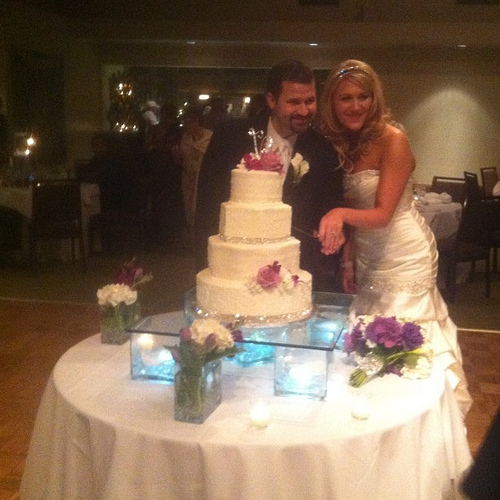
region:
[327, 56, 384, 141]
head of a person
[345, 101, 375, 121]
nose of a person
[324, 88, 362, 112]
eye of a person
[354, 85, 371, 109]
eye of a person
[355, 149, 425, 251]
arm of a person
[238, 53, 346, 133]
head of a person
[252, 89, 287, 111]
ear of a person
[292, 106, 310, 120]
nose of a person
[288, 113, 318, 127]
mouth of a person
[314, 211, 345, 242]
hand of a person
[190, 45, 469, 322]
Bride and groom cutting wedding cake.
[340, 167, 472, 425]
Bride wearing a wedding dress.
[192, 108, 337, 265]
Groom wearing black suit.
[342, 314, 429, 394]
Purple flower bouquet lying on table.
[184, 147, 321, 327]
Four tier wedding cake sitting on table.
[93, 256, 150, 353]
White and purple flowers in vase on table.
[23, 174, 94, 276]
Back of chair pushed up to table.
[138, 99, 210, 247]
Two women standing in background.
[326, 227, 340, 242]
Woman wearing wedding ring on finger.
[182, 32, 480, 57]
Lights mounted in ceiling of room.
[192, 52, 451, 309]
a bride and groom on their wedding day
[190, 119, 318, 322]
a four-tiered wedding cake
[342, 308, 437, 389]
a purple and white floral bouquet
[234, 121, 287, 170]
decorations on top of the wedding cake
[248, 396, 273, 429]
a small candle on the table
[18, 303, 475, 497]
a white tablecloth on the table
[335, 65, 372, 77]
a sparkly headband in the bride's hair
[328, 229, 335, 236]
a ring on the bride's finger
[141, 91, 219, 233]
people coming into the reception hall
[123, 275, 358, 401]
a glass structure with a wedding cake on it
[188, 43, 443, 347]
two people holding a knife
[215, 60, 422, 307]
two married people holding knife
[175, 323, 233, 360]
white flowers in vase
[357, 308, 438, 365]
purple flowers on table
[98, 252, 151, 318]
white and purple flowers in vase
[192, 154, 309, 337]
large white wedding cake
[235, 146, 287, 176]
pink and purple wedding cake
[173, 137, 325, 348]
four tiered wedding cake on stand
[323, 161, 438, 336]
long white wedding dress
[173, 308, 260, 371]
white and purple flowers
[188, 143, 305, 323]
large white wedding cake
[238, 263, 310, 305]
flowers on bottom of cake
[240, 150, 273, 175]
flowers on top of cake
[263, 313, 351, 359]
glass base of cake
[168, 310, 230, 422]
flowers in vase on table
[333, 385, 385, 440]
candles on side of table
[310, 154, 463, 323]
long white wedding dress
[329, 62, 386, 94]
head band on head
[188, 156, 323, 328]
a wedding cake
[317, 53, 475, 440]
a woman wearing a white dress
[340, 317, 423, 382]
purple flowers on the table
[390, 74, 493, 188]
a spotlight shinning on the wall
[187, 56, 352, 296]
man wearing a black suit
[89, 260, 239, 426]
two bags on the table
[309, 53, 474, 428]
a woman with blonde hair